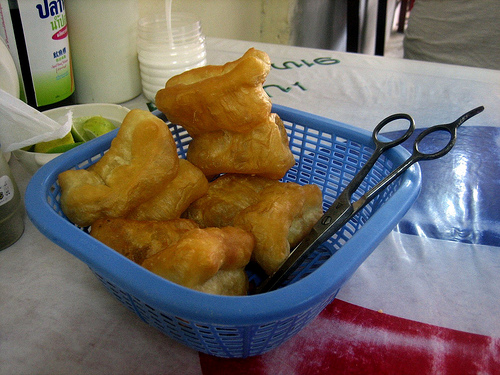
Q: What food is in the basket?
A: Fried doughnuts.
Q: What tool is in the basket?
A: Scissors.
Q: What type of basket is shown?
A: Blue square shape.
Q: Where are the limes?
A: White container.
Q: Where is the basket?
A: Cloth covered table.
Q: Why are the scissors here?
A: Cut the food.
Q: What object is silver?
A: The scissors.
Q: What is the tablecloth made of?
A: Plastic.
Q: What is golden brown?
A: The fried food.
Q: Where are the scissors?
A: In the blue basket.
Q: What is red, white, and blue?
A: The tablecloth.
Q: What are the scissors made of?
A: Metal.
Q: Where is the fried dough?
A: In the blue basket.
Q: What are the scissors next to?
A: The fried dough.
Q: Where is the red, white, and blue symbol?
A: On the tablecloth.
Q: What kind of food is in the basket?
A: Brown pastries.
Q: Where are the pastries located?
A: In the blue plastic basket on the table.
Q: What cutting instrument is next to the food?
A: The black scissors in the basket.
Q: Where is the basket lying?
A: On a red white and blue circle.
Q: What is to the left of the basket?
A: A white bowl with green slices.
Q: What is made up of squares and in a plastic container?
A: The holes in the side of the basket.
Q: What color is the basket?
A: Blue.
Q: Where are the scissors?
A: In the blue basket.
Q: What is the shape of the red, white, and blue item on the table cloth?
A: A circle.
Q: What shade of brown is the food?
A: Golden brown.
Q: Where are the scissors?
A: By the food.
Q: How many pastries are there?
A: 4.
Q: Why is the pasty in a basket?
A: To hold the items.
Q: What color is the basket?
A: Blue.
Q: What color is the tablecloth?
A: Red white and blue.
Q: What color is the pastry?
A: Brown.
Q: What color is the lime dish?
A: White.